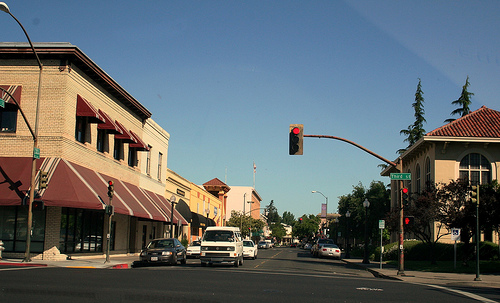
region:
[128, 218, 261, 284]
Cars in the foreground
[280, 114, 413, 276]
A traffic light in the foreground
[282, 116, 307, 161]
Traffic light is on red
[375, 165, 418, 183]
A street sign in the foreground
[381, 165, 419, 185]
The street sign is green in color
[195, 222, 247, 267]
A white van in the foreground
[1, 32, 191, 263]
A building in the foreground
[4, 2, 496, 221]
The sky is clear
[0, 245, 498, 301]
The concrete streets are dark gray in color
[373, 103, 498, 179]
The roof of the building is brown in color.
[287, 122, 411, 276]
Stop light on a pole over a street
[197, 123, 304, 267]
Cars waiting at a red stop light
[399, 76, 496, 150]
Two tall green trees behind a building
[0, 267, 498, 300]
Black asphalt street with white lines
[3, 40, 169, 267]
Multistory city building made of bricks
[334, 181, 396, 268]
Green trees in a row beside the street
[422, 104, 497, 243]
Building with a red roof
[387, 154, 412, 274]
Street sign on a metal pole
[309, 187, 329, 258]
Street light hanging over parked cars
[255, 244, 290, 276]
Yellow dotted lines down the center of the street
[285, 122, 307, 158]
three light traffic signal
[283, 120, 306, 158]
lit red light on signal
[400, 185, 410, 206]
red traffic light on tall pole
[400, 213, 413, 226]
don't walk signal on pole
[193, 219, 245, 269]
front end of white van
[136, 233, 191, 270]
black car parked at curb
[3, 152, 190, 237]
brown awning on brick building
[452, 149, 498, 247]
arched window on right of building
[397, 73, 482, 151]
tops of pine trees beyond building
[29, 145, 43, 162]
green street sign on metal pole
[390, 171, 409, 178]
green street sign with white letters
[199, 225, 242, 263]
white van on the street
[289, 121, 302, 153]
metal street light on red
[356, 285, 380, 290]
man hole cover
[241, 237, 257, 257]
white car behind van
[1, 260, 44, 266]
red paint on the curb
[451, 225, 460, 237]
sign with white and blue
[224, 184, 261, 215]
square building in the distance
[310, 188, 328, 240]
tall street light